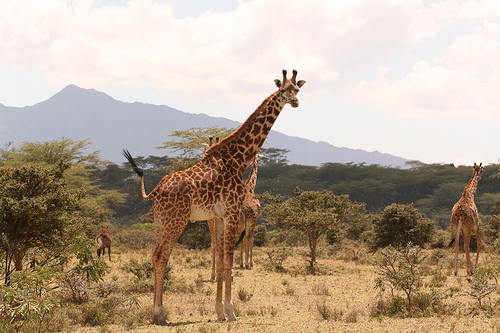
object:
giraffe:
[120, 69, 308, 322]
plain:
[1, 242, 499, 333]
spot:
[252, 124, 260, 136]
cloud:
[0, 0, 500, 164]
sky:
[1, 0, 500, 165]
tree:
[260, 185, 372, 276]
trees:
[2, 160, 85, 271]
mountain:
[1, 82, 427, 170]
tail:
[122, 149, 153, 202]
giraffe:
[449, 162, 485, 278]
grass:
[234, 285, 254, 301]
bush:
[365, 201, 439, 317]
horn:
[281, 69, 289, 81]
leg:
[153, 219, 184, 324]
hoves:
[224, 304, 237, 319]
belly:
[188, 204, 214, 220]